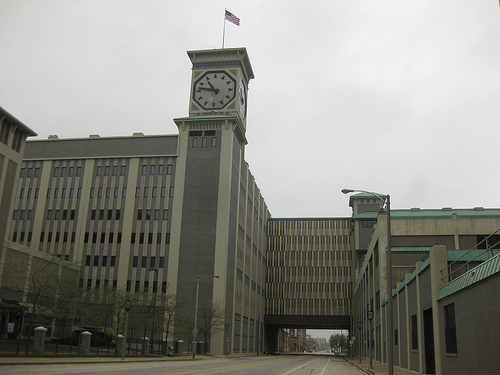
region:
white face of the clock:
[193, 68, 236, 113]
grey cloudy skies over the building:
[290, 81, 490, 173]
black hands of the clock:
[195, 82, 220, 93]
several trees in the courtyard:
[26, 268, 216, 357]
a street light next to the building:
[348, 184, 407, 371]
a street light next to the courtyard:
[186, 272, 224, 361]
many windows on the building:
[5, 147, 180, 296]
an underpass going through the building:
[258, 318, 361, 363]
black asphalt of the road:
[153, 358, 343, 373]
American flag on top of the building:
[215, 8, 245, 48]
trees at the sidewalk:
[9, 261, 253, 349]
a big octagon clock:
[180, 62, 261, 130]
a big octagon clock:
[178, 53, 230, 119]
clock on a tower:
[187, 46, 252, 118]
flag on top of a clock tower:
[219, 6, 239, 46]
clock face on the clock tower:
[192, 70, 236, 107]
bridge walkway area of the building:
[266, 215, 353, 325]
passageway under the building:
[275, 324, 349, 357]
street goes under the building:
[5, 351, 368, 373]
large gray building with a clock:
[0, 47, 496, 373]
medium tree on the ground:
[187, 299, 229, 361]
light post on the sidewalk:
[191, 272, 218, 363]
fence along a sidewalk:
[0, 322, 207, 361]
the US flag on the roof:
[201, 9, 253, 43]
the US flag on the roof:
[213, 14, 245, 47]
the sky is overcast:
[281, 68, 419, 168]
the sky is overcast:
[39, 24, 121, 64]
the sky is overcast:
[297, 78, 376, 121]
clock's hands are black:
[178, 70, 264, 122]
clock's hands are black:
[189, 67, 237, 109]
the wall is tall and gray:
[179, 152, 219, 306]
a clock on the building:
[172, 63, 242, 120]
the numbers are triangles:
[188, 62, 237, 111]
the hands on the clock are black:
[193, 73, 224, 102]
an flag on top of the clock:
[175, 2, 269, 69]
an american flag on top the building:
[175, 0, 266, 42]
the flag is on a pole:
[183, 0, 251, 42]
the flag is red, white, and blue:
[190, 0, 264, 41]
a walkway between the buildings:
[247, 212, 376, 349]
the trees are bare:
[22, 264, 226, 333]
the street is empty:
[88, 335, 336, 372]